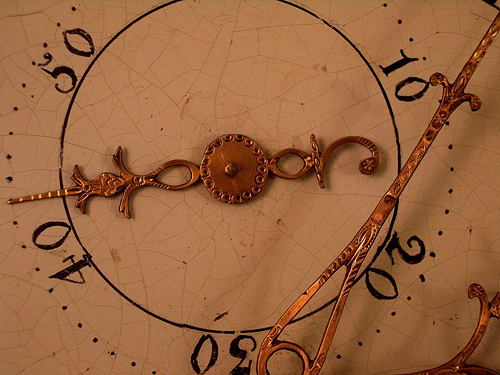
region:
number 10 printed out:
[377, 41, 434, 115]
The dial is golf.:
[38, 136, 388, 219]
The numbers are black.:
[32, 224, 130, 306]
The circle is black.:
[19, 40, 442, 325]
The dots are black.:
[419, 152, 469, 237]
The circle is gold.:
[192, 122, 293, 225]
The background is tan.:
[105, 77, 277, 112]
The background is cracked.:
[122, 32, 302, 94]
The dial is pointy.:
[7, 185, 74, 223]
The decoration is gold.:
[247, 28, 448, 373]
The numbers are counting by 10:
[17, 13, 418, 373]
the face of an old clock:
[0, 7, 495, 370]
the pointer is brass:
[3, 127, 388, 204]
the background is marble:
[5, 8, 484, 342]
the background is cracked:
[14, 18, 470, 358]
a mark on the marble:
[204, 295, 239, 323]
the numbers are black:
[16, 10, 459, 373]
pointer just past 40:
[5, 110, 397, 214]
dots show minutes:
[0, 3, 482, 351]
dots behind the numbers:
[5, 4, 488, 357]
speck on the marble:
[202, 301, 242, 333]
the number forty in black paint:
[22, 215, 113, 290]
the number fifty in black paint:
[20, 15, 110, 95]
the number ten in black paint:
[355, 40, 455, 120]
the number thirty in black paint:
[180, 325, 275, 370]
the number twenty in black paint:
[355, 220, 440, 310]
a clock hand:
[0, 125, 390, 220]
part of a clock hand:
[240, 5, 450, 370]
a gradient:
[0, 85, 35, 175]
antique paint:
[161, 240, 284, 290]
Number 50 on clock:
[29, 27, 114, 99]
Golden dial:
[8, 131, 400, 226]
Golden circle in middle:
[204, 124, 276, 214]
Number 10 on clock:
[381, 44, 436, 116]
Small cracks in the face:
[138, 199, 188, 246]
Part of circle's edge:
[51, 26, 123, 273]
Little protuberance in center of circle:
[223, 160, 242, 180]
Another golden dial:
[258, 22, 482, 373]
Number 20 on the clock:
[368, 220, 445, 300]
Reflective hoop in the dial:
[270, 141, 318, 179]